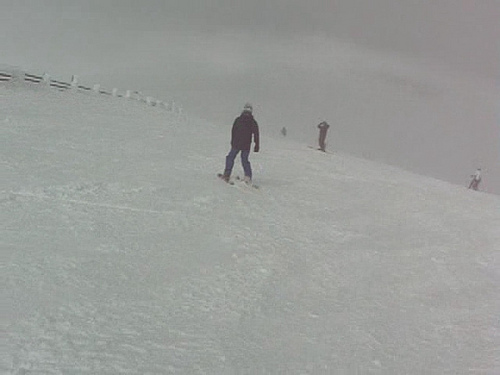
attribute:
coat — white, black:
[224, 124, 263, 146]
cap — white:
[243, 98, 255, 110]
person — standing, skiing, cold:
[201, 95, 260, 172]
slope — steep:
[21, 98, 77, 141]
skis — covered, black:
[212, 181, 269, 185]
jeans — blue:
[211, 160, 258, 176]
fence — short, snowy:
[20, 72, 78, 90]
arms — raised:
[310, 116, 331, 128]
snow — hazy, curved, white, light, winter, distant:
[30, 168, 129, 199]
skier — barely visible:
[454, 168, 494, 194]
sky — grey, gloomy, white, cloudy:
[183, 9, 239, 28]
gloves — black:
[251, 142, 259, 150]